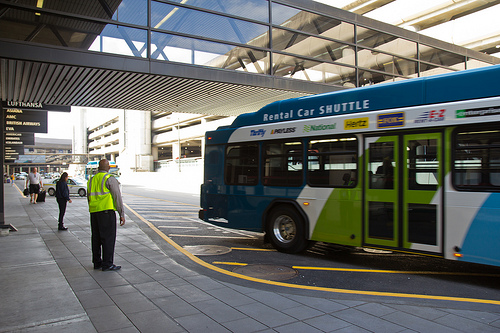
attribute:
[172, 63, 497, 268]
bus — blue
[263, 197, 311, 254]
wheel — black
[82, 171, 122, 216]
vest — green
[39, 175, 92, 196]
car — white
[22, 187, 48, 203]
luggage — black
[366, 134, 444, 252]
door — green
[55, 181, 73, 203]
jacket — blue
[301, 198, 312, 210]
light — orange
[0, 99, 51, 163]
signs — black